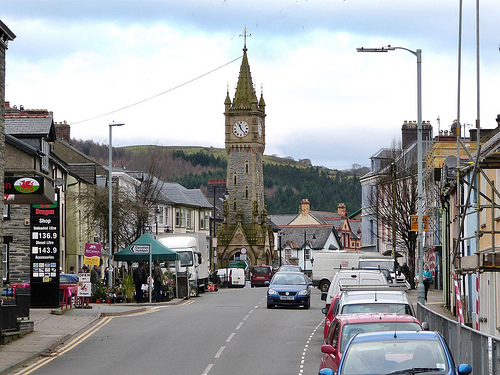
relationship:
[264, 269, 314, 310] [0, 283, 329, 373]
car driving on road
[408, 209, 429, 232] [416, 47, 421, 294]
sign on pole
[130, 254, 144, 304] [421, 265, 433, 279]
person wearing shirt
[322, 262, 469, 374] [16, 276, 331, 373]
cars parked on side of street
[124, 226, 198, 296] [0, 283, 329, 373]
tent on side of road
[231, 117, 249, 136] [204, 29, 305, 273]
clock in tower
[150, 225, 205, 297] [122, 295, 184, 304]
truck at curb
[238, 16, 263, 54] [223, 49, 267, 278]
weather vane on tower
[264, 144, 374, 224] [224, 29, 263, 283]
trees behind building